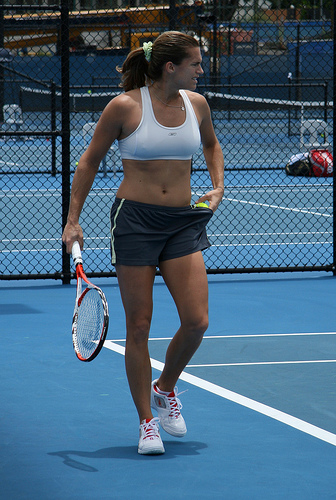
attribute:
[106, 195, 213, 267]
shorts — black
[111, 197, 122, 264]
line — white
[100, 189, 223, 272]
shorts — blue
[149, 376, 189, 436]
shoe — white, tennis shoe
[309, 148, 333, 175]
bag — red, white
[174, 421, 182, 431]
white — white , red 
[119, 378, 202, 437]
shoes — white, red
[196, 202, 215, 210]
tennis ball — yellow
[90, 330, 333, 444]
lines — white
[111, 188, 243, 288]
shorts — gray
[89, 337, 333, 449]
line — white